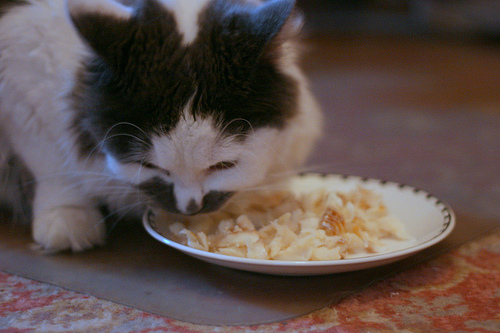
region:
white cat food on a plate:
[240, 206, 333, 263]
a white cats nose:
[177, 185, 202, 207]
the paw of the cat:
[43, 200, 89, 250]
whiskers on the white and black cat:
[231, 125, 262, 156]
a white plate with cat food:
[227, 180, 467, 251]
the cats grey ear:
[65, 3, 125, 24]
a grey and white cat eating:
[1, 25, 297, 196]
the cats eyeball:
[202, 152, 237, 170]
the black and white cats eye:
[130, 155, 171, 180]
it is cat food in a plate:
[262, 196, 393, 249]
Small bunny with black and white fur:
[0, 3, 321, 245]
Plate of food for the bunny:
[145, 171, 455, 276]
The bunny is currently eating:
[0, 0, 321, 248]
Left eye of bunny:
[205, 161, 236, 172]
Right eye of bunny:
[137, 160, 170, 171]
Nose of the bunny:
[170, 171, 205, 208]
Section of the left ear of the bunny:
[197, 2, 294, 57]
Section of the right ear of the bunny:
[65, 1, 181, 56]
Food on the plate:
[150, 185, 410, 261]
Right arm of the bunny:
[31, 194, 107, 260]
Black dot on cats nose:
[171, 189, 209, 218]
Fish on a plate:
[238, 223, 360, 251]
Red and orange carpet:
[392, 292, 492, 332]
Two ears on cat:
[64, 2, 300, 67]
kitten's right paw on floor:
[25, 186, 117, 258]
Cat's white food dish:
[153, 233, 485, 278]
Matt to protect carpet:
[338, 77, 490, 167]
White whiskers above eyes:
[94, 124, 274, 167]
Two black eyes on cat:
[129, 148, 242, 182]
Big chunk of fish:
[315, 207, 362, 241]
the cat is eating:
[85, 17, 412, 254]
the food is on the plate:
[158, 168, 393, 258]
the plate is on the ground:
[137, 158, 437, 326]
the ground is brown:
[105, 254, 215, 311]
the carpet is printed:
[20, 280, 96, 329]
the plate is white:
[125, 157, 410, 298]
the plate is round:
[163, 129, 481, 281]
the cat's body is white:
[7, 12, 394, 302]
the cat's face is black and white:
[57, 32, 287, 194]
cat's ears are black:
[52, 10, 303, 162]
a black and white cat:
[53, 2, 335, 237]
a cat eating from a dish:
[24, 2, 483, 308]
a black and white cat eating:
[52, 2, 498, 311]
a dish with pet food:
[138, 153, 483, 293]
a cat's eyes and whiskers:
[83, 100, 273, 184]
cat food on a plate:
[255, 193, 477, 300]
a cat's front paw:
[7, 139, 123, 283]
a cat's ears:
[57, 1, 327, 75]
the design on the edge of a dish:
[405, 173, 487, 263]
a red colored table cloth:
[337, 240, 499, 331]